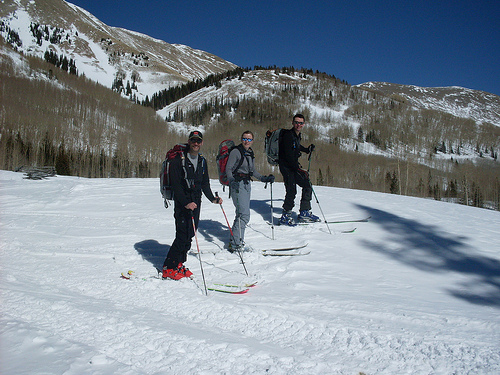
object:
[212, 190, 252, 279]
pole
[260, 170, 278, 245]
pole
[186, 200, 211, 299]
pole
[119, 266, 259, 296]
ski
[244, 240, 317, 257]
ski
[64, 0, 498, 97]
skies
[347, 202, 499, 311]
shadow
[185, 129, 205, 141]
hat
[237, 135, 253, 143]
glasses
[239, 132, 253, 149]
face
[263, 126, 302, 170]
pack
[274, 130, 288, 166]
back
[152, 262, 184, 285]
boots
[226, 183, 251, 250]
pants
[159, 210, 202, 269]
pants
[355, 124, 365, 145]
trees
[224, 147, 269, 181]
jacket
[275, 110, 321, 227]
man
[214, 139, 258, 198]
backpack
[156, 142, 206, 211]
backpack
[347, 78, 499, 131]
range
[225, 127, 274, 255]
man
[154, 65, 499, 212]
mountain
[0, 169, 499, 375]
snow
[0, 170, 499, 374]
hill side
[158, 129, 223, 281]
man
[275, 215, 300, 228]
snow boots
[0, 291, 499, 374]
tracks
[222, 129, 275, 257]
woman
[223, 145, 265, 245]
outfit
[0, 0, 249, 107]
mountains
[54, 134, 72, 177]
trees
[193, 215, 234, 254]
shadow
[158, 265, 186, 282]
skiboots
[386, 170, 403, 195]
tree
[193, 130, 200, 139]
decal